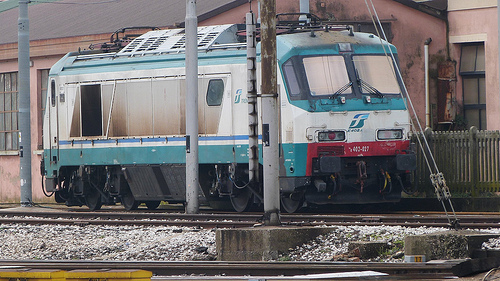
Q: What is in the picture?
A: A train.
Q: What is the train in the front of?
A: A building.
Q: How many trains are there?
A: One.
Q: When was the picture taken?
A: During the day.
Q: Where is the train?
A: On outside.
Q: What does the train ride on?
A: Tracks.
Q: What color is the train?
A: Red, white and blue.